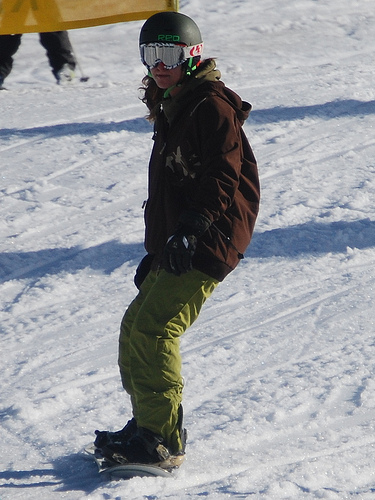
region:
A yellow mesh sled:
[1, 1, 186, 39]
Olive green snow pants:
[108, 257, 237, 467]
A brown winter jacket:
[135, 91, 274, 275]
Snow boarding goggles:
[132, 39, 211, 70]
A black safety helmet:
[131, 11, 209, 86]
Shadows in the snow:
[238, 84, 373, 301]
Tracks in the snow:
[225, 287, 367, 497]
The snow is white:
[7, 142, 139, 232]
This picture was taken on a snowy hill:
[7, 5, 368, 489]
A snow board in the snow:
[66, 435, 189, 485]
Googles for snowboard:
[132, 39, 201, 63]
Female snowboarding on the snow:
[75, 3, 229, 472]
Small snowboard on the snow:
[86, 443, 192, 480]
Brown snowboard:
[130, 75, 263, 278]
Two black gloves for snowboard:
[121, 233, 202, 278]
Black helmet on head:
[139, 10, 201, 47]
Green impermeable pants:
[106, 248, 226, 433]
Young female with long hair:
[96, 1, 262, 483]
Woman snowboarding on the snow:
[91, 4, 266, 487]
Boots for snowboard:
[90, 403, 196, 466]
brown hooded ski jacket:
[139, 71, 272, 304]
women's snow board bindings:
[92, 416, 205, 468]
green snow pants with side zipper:
[110, 245, 237, 469]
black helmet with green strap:
[132, 4, 218, 107]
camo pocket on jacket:
[155, 129, 218, 195]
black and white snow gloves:
[154, 206, 224, 279]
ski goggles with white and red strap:
[134, 40, 215, 72]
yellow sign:
[0, 1, 207, 51]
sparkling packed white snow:
[219, 294, 366, 493]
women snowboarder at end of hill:
[118, 0, 249, 495]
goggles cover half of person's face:
[122, 35, 200, 90]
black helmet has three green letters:
[120, 6, 217, 43]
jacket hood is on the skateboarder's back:
[125, 75, 290, 127]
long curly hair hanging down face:
[129, 57, 176, 129]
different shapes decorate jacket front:
[161, 137, 206, 188]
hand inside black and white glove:
[152, 217, 222, 277]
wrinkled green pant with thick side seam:
[108, 250, 217, 441]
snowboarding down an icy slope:
[64, 22, 269, 487]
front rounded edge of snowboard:
[86, 455, 191, 481]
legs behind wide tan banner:
[3, 5, 117, 98]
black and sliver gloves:
[157, 218, 200, 293]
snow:
[234, 340, 316, 442]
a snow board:
[105, 418, 181, 482]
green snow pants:
[136, 316, 198, 441]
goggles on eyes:
[129, 49, 208, 65]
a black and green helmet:
[135, 11, 206, 41]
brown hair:
[136, 75, 160, 115]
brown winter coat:
[173, 96, 238, 271]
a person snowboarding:
[99, 12, 268, 485]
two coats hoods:
[205, 53, 261, 129]